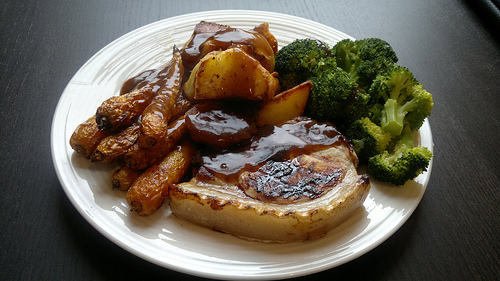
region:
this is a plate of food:
[65, 17, 472, 249]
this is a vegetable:
[361, 68, 417, 136]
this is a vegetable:
[276, 34, 335, 73]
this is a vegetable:
[305, 80, 362, 126]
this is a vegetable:
[329, 108, 384, 150]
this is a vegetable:
[143, 50, 183, 150]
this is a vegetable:
[81, 85, 162, 132]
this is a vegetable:
[76, 111, 127, 188]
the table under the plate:
[2, 0, 498, 277]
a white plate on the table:
[50, 7, 436, 278]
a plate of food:
[49, 8, 431, 280]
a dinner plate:
[48, 8, 434, 277]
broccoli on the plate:
[298, 39, 438, 150]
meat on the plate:
[201, 148, 351, 221]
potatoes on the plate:
[191, 19, 264, 88]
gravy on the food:
[196, 91, 303, 159]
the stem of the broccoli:
[386, 98, 403, 126]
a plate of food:
[93, 48, 430, 252]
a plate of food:
[80, 0, 440, 267]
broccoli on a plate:
[286, 40, 334, 67]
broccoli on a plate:
[359, 42, 396, 67]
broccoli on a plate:
[320, 78, 360, 105]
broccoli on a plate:
[371, 60, 414, 96]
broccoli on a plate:
[405, 84, 442, 119]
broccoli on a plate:
[343, 121, 390, 151]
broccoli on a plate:
[371, 142, 400, 175]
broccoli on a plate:
[403, 132, 443, 179]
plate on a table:
[48, 16, 456, 269]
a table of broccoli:
[34, 8, 450, 253]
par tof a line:
[396, 198, 440, 234]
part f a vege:
[402, 130, 417, 152]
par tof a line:
[292, 130, 317, 170]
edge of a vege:
[361, 115, 404, 215]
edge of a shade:
[389, 231, 407, 256]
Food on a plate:
[44, 0, 445, 279]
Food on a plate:
[42, 3, 452, 270]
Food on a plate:
[48, 3, 428, 279]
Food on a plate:
[41, 0, 453, 279]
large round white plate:
[49, 8, 435, 277]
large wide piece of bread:
[168, 172, 371, 242]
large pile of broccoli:
[281, 33, 436, 189]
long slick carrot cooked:
[140, 46, 187, 148]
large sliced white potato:
[176, 50, 277, 103]